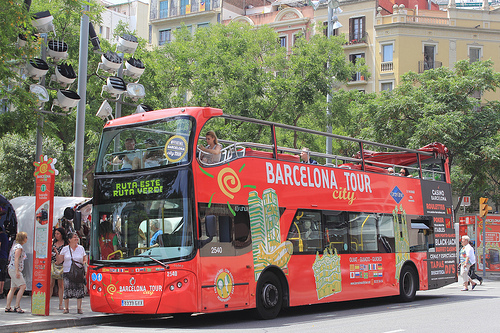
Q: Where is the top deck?
A: Above the firsy.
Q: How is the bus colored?
A: Red.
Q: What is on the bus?
A: Pictures.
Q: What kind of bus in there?
A: Double decker.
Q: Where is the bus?
A: Street.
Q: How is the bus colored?
A: Red.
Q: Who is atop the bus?
A: Passengers.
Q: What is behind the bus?
A: Buidings.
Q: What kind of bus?
A: Double decker.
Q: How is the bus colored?
A: Red.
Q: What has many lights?
A: Poles.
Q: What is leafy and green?
A: Trees.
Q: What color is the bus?
A: Red.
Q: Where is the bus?
A: By the curb.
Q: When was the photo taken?
A: Daytime.